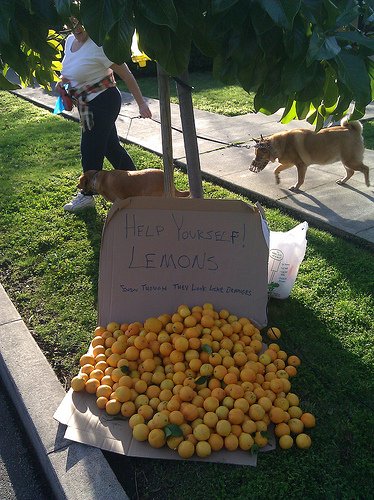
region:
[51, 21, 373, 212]
a woman walking two dogs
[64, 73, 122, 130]
a woman with a plaid shirt around her waist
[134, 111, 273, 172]
a dog on a leash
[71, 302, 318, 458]
a heap of lemons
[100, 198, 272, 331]
a cardboard propped on a tree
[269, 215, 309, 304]
a white plastic bag on the grass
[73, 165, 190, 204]
a small brown dog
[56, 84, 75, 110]
woman carrying a small red bag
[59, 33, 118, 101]
woman wearing a white shirt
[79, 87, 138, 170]
woman wearing blue pants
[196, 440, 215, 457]
lemon on a cardboard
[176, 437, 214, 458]
two small lemons on a cardboard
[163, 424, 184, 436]
green lemon leaves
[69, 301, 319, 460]
large bunch of lemons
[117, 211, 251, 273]
cardboard sign reading Help Yourself! Lemons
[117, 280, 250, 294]
small handwriting on a cardboard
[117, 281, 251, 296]
small handwritten text reading even though they look like oranges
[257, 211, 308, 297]
white plastic bag with a green print on it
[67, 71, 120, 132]
plaid sweater tied around a woman's waist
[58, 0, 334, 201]
woman pulling two dogs on a leash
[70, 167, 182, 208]
the dog is brown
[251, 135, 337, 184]
the dog is brown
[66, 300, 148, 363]
lemons on the ground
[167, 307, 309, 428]
lemons on the ground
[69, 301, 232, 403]
lemons on the ground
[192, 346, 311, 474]
lemons on the ground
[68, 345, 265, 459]
lemons on the ground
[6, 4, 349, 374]
This photo is along a sidewalk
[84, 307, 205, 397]
These are a bunch of lemons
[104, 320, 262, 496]
The lemons are yellow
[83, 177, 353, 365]
This is a cardboard box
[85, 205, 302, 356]
The writing is in blue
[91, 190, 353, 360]
The cardboard box is brown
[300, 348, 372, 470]
The ground here is made of grass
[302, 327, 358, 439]
The grass is very green and lush here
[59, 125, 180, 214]
This dog is on a leash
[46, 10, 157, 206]
The woman is walking the dogs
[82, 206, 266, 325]
a card board sign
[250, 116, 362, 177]
a dog in a muzzle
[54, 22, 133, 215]
a woman walking a dog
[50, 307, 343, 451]
lemons on the grass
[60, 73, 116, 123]
a shirt tied around waist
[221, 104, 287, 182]
a concrete side walk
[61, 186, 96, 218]
a white tennis shoe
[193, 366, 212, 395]
leaves on a lemon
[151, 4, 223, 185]
a pole behind a box lid